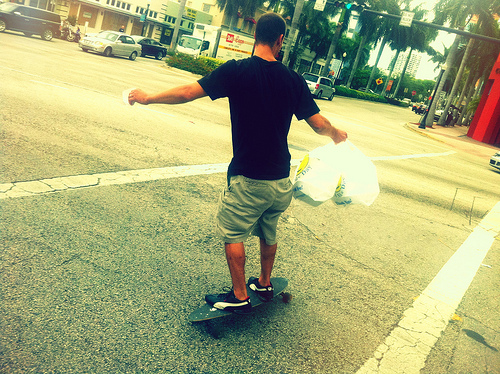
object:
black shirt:
[195, 55, 320, 188]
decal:
[292, 139, 347, 207]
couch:
[187, 276, 288, 321]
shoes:
[205, 275, 275, 315]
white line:
[0, 152, 234, 205]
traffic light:
[341, 0, 358, 11]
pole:
[322, 0, 500, 45]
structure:
[465, 47, 500, 143]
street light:
[418, 60, 449, 128]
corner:
[403, 112, 500, 158]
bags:
[293, 141, 341, 208]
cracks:
[0, 169, 103, 198]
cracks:
[353, 305, 449, 374]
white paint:
[0, 145, 464, 201]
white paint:
[348, 197, 500, 374]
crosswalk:
[0, 147, 499, 374]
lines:
[348, 195, 500, 373]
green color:
[343, 1, 351, 11]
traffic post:
[317, 0, 500, 44]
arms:
[146, 59, 231, 105]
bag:
[332, 140, 380, 207]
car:
[78, 29, 143, 59]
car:
[300, 72, 336, 101]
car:
[132, 35, 167, 60]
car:
[0, 1, 61, 40]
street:
[0, 18, 499, 373]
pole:
[167, 0, 190, 55]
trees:
[215, 0, 500, 131]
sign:
[375, 76, 383, 86]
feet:
[203, 278, 275, 314]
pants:
[214, 174, 295, 247]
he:
[129, 11, 348, 318]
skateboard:
[189, 271, 292, 336]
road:
[0, 20, 500, 373]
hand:
[333, 129, 348, 145]